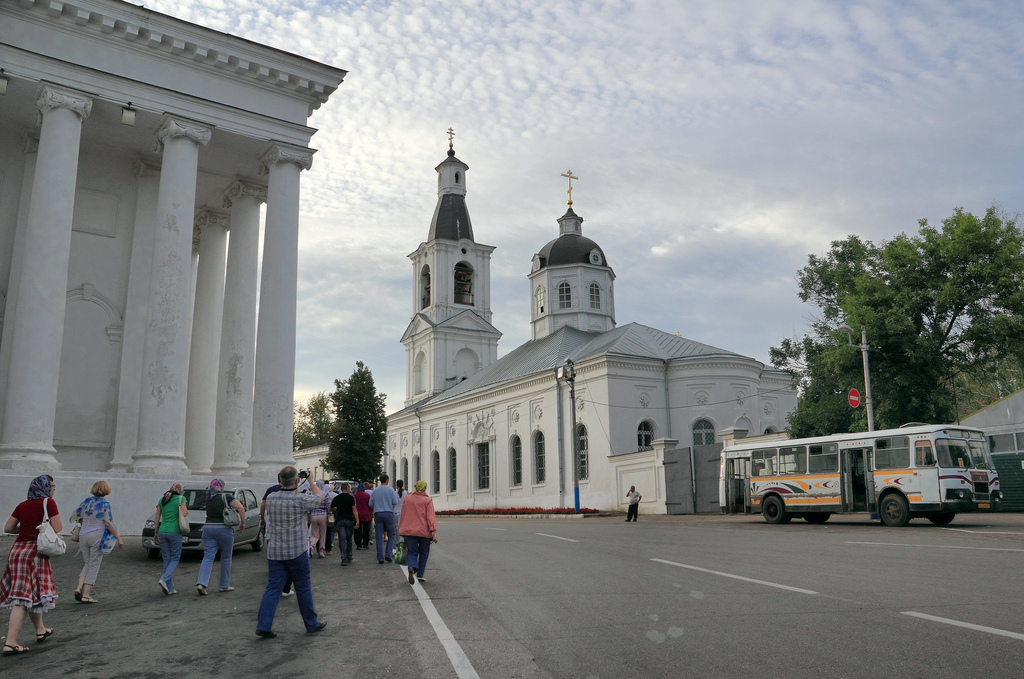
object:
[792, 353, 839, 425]
leaves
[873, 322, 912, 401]
leaves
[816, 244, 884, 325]
leaves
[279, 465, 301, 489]
head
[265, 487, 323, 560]
shirt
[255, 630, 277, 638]
foot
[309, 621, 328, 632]
foot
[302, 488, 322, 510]
elbow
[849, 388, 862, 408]
sign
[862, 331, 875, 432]
pole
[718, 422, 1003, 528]
bus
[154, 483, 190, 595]
woman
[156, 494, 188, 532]
shirt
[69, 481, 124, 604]
woman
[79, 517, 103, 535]
shirt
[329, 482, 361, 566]
man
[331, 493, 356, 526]
shirt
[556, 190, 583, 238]
steeple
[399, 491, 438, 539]
jacket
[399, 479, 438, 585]
person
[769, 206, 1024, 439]
leaves